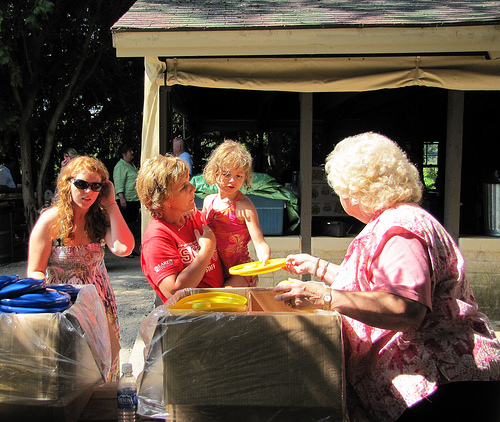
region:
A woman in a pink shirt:
[272, 132, 499, 419]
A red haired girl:
[27, 156, 135, 381]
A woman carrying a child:
[139, 137, 270, 311]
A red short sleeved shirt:
[139, 211, 228, 302]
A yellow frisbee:
[229, 257, 290, 275]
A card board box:
[157, 284, 348, 419]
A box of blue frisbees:
[2, 274, 101, 420]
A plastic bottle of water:
[117, 362, 139, 420]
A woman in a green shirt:
[114, 144, 139, 259]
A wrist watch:
[323, 284, 331, 305]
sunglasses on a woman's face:
[69, 174, 103, 192]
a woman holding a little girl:
[137, 156, 224, 287]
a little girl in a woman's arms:
[203, 139, 270, 285]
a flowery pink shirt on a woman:
[332, 200, 499, 412]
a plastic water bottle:
[115, 360, 135, 418]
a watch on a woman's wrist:
[322, 283, 332, 309]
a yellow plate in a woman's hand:
[228, 254, 288, 277]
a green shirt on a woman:
[112, 158, 138, 203]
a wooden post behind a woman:
[441, 88, 466, 243]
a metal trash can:
[482, 176, 498, 238]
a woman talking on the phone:
[35, 137, 133, 336]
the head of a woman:
[57, 156, 109, 248]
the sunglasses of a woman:
[60, 163, 102, 194]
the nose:
[72, 188, 95, 197]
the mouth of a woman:
[72, 193, 96, 203]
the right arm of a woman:
[12, 199, 64, 276]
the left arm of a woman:
[97, 215, 150, 264]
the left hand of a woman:
[86, 183, 119, 213]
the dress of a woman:
[55, 229, 109, 270]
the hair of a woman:
[142, 159, 163, 179]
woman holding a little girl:
[124, 120, 290, 339]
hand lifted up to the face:
[87, 173, 138, 258]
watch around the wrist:
[321, 288, 337, 312]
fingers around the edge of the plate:
[278, 253, 290, 273]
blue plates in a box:
[0, 262, 122, 420]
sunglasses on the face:
[71, 172, 101, 193]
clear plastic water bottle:
[111, 361, 150, 420]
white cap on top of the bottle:
[114, 360, 139, 376]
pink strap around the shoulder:
[228, 188, 245, 208]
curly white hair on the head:
[322, 128, 427, 208]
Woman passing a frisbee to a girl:
[227, 128, 498, 420]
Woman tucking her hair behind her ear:
[25, 154, 135, 387]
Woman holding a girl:
[134, 135, 271, 306]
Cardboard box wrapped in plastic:
[131, 285, 350, 419]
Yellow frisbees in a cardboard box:
[166, 285, 250, 317]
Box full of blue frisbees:
[0, 269, 114, 420]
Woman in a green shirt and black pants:
[110, 138, 141, 261]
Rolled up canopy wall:
[164, 51, 499, 94]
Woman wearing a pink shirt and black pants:
[270, 128, 498, 420]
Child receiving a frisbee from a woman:
[199, 138, 271, 297]